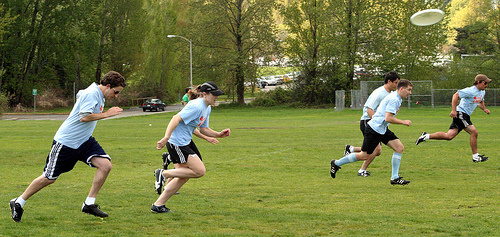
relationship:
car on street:
[131, 92, 173, 117] [123, 89, 165, 125]